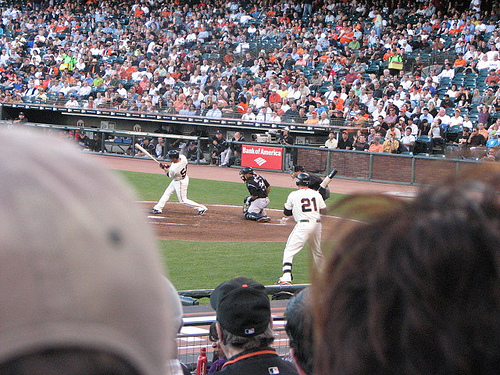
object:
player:
[144, 147, 209, 217]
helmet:
[164, 148, 181, 161]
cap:
[208, 275, 271, 335]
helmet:
[236, 164, 253, 181]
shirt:
[278, 187, 329, 222]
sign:
[240, 142, 283, 172]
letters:
[270, 149, 279, 158]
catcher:
[235, 164, 273, 222]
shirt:
[239, 172, 270, 202]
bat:
[130, 140, 168, 175]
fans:
[393, 126, 417, 153]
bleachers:
[0, 0, 499, 190]